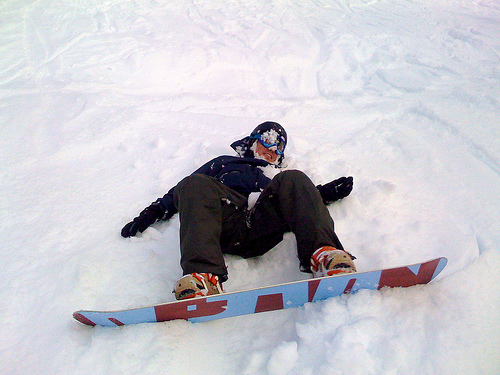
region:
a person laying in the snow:
[73, 107, 440, 321]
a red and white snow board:
[77, 256, 446, 326]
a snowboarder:
[71, 102, 437, 324]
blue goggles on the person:
[251, 123, 288, 150]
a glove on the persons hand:
[327, 172, 351, 196]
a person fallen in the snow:
[75, 119, 457, 342]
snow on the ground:
[268, 314, 409, 364]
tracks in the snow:
[20, 43, 457, 115]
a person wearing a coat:
[104, 113, 401, 318]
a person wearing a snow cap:
[120, 98, 365, 286]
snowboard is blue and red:
[82, 245, 486, 334]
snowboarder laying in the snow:
[102, 79, 437, 341]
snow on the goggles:
[246, 122, 306, 159]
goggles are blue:
[254, 132, 292, 156]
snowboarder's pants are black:
[173, 159, 366, 275]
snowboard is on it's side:
[53, 256, 499, 338]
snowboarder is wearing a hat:
[236, 107, 302, 145]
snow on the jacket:
[209, 141, 351, 221]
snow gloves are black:
[91, 172, 405, 241]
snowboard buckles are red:
[154, 233, 379, 319]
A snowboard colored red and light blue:
[70, 263, 455, 330]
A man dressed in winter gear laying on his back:
[137, 115, 360, 289]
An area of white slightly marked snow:
[67, 13, 189, 113]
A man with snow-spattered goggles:
[233, 108, 293, 167]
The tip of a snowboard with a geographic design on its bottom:
[370, 250, 455, 300]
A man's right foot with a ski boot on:
[167, 269, 234, 301]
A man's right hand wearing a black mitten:
[112, 191, 169, 241]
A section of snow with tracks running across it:
[183, 2, 307, 72]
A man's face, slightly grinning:
[233, 118, 293, 166]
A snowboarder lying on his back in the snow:
[142, 109, 384, 323]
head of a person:
[229, 102, 300, 164]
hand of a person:
[305, 166, 359, 200]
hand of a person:
[122, 198, 160, 248]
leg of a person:
[172, 265, 226, 319]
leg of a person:
[169, 188, 223, 270]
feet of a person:
[299, 255, 346, 289]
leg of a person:
[267, 161, 327, 258]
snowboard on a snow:
[53, 268, 495, 335]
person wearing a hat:
[89, 81, 389, 333]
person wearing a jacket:
[113, 62, 368, 324]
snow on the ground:
[7, 86, 134, 223]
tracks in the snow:
[293, 320, 427, 373]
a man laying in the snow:
[125, 120, 380, 280]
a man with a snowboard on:
[70, 253, 454, 316]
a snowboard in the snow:
[73, 256, 440, 310]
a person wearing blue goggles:
[121, 125, 370, 302]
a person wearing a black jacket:
[128, 114, 350, 312]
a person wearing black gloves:
[111, 118, 337, 278]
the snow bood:
[169, 273, 226, 300]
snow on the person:
[240, 148, 273, 199]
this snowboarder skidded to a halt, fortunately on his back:
[22, 111, 493, 348]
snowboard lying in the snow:
[63, 96, 469, 345]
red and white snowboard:
[66, 248, 462, 325]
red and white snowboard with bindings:
[58, 240, 459, 338]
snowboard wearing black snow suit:
[97, 101, 383, 268]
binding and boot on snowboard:
[168, 257, 238, 322]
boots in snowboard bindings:
[168, 231, 365, 303]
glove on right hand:
[118, 189, 172, 249]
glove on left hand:
[317, 171, 367, 208]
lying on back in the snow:
[50, 106, 476, 338]